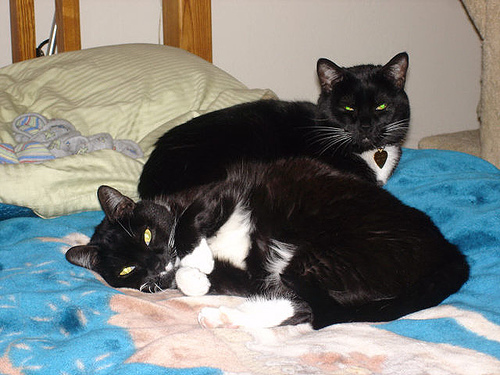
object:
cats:
[131, 49, 417, 203]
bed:
[0, 0, 500, 375]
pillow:
[0, 40, 280, 171]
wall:
[0, 0, 482, 151]